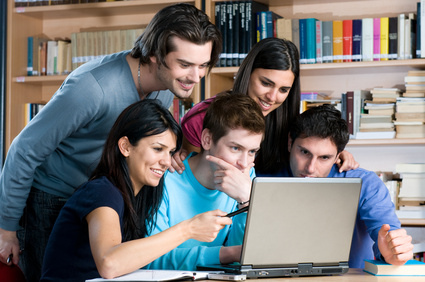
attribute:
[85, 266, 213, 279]
book — opened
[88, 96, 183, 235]
hair — dark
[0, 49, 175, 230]
shirt — long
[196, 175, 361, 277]
laptop — white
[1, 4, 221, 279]
man — light skinned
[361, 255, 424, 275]
book — blue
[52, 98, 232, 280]
lady — light skinned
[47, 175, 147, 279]
shirt — dark blue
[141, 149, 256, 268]
shirt — light blue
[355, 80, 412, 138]
books — a stack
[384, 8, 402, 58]
book — one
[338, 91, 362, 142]
book — one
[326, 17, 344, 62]
book — one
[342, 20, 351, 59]
book — one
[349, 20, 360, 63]
book — one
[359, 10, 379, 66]
book — one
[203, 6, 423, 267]
shelf — book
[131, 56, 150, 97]
necklace — chain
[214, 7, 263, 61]
set — book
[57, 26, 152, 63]
set — book, large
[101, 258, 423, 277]
table — large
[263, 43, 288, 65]
hair — black, female